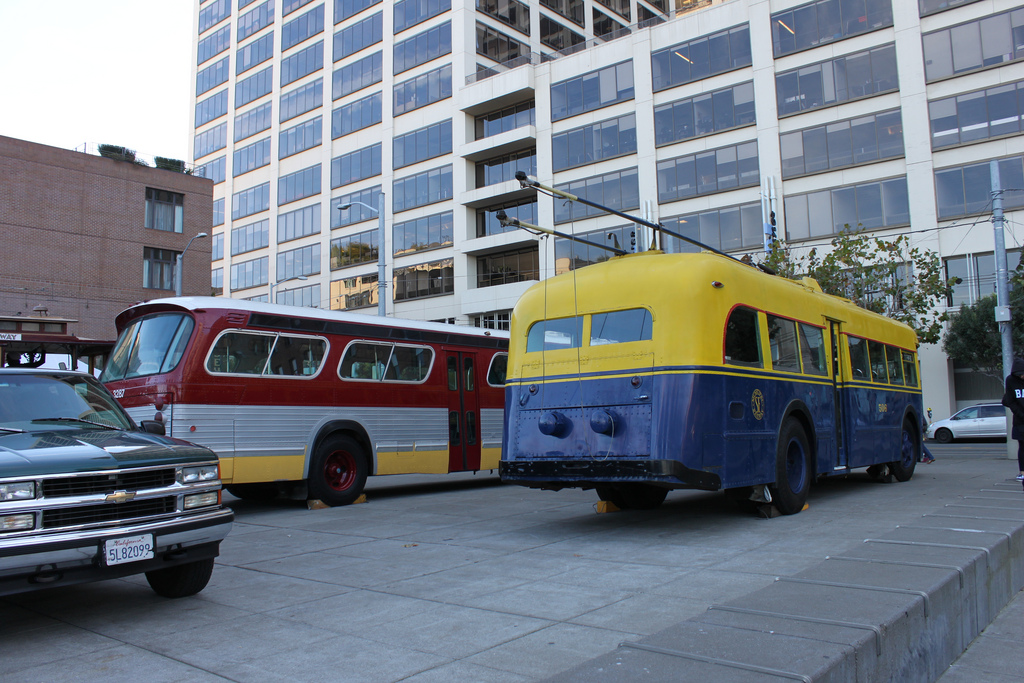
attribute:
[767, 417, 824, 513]
tire — black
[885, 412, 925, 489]
tire — black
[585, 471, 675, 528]
tire — black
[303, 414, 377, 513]
tire — black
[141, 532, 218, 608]
tire — black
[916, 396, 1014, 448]
van — grey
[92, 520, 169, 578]
license plate — blue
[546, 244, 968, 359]
tree — green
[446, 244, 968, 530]
bus — yellow and blue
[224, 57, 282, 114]
window — glass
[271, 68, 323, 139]
window — glass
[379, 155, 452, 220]
window — glass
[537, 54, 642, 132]
window — glass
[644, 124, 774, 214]
window — glass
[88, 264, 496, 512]
bus — red and white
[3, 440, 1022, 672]
concrete — gray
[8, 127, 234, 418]
building — brown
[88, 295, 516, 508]
bus — red yellow and silver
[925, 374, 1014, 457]
car — silver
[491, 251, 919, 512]
bus — blue and yellow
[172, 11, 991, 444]
building — big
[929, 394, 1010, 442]
car — silver